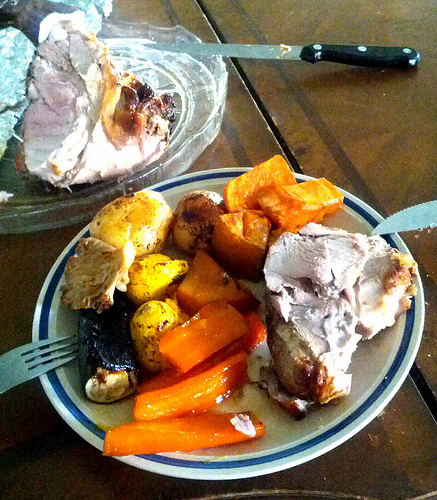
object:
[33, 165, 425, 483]
dish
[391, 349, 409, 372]
border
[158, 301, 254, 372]
carrot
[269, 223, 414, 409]
meat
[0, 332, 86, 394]
fork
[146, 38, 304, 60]
knife blade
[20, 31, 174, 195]
meat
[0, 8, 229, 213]
container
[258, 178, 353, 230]
sweet potato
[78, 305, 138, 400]
zucchini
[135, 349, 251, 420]
carrot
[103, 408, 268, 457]
carrot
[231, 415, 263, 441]
meat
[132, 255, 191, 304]
dollop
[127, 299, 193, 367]
dollop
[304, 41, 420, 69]
knife handle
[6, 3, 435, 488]
table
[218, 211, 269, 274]
sweet potato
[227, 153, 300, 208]
sweet potato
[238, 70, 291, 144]
gap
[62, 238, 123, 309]
food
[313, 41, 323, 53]
circle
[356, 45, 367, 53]
circle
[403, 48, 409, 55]
circle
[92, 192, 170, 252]
food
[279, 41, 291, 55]
food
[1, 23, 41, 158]
foil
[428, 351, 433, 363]
crumb